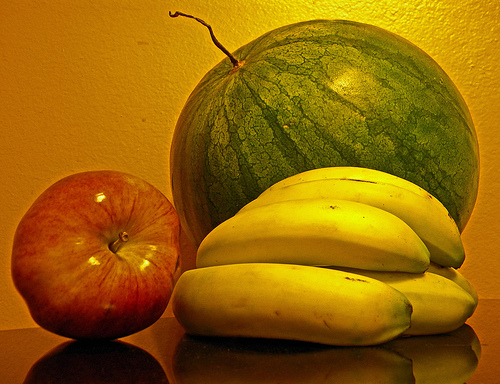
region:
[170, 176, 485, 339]
Bananas on a table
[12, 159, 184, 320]
apple on the table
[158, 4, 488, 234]
watermelon on the table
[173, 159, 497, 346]
five bananas on a table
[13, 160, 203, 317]
red table on a table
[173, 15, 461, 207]
green watermelon on a table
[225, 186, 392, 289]
yellow bananas on a table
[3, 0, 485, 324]
fruit on a the table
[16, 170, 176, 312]
shiny red apple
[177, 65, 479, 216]
large watermelon on a table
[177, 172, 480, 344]
bananas on a table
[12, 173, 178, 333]
apples on a table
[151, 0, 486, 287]
watermelon on a table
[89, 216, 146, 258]
stem of an apple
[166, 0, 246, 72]
stem of a watermelon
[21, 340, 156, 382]
reflections from the counter top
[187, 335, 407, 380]
reflections of the banan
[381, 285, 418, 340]
skin of a banan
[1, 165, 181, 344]
red apple on table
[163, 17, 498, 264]
a round watermelon on table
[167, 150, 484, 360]
bananas beside the apple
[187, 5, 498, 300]
a green circle watermelon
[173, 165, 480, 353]
A bunch of yellow bananas.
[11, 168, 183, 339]
A shiny red apple.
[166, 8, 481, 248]
A round green watermelon.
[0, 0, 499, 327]
A yellow textured wall.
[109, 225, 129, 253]
A small apple stem.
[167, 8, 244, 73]
A dried up stem.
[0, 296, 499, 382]
A shiny brown tabletop.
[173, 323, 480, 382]
Reflection of some bananas.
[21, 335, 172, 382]
Reflection of an apple.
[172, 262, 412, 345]
One yellow ripe banana.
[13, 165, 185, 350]
A shiny red apple on the wooden table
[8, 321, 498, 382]
The wooden table is polished and shining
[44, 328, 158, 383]
Reflection of the apple on the wooden table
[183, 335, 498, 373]
Reflection of yellow bananas on the table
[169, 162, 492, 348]
A bundle of ripe yellow bananas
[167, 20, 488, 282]
A large green watermelon on the table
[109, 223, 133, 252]
A short brown stem on the apple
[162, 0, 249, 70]
A long brown stem on the green watermelon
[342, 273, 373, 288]
A small brown spot on the banana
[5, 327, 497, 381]
A polished wooden table beneath the fruit